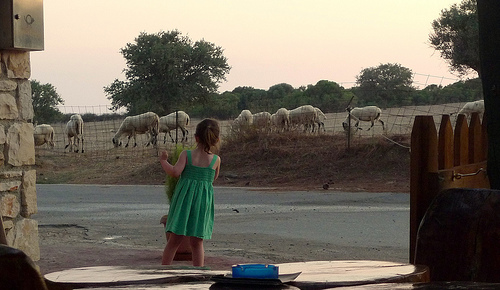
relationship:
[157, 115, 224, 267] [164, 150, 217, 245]
girl wearing dress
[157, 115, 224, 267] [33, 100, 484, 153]
girl watching flock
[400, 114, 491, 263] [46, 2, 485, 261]
gate at entrance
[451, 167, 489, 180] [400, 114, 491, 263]
handle on gate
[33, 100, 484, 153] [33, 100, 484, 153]
flock of flock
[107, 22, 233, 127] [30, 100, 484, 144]
tree in field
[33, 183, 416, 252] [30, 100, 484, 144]
road beside field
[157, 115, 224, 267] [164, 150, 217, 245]
girl in dress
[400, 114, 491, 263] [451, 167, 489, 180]
gate with latch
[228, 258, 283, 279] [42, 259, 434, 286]
ashtray on table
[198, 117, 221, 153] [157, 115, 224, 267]
hair on girl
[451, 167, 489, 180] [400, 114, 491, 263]
hook on gate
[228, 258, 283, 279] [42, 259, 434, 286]
ashtray sitting on table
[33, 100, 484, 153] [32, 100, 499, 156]
flock behind fence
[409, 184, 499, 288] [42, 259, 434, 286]
chair at table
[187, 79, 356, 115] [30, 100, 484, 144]
trees in field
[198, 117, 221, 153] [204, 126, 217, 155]
hair in ponytail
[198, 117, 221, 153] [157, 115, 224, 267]
hair of girl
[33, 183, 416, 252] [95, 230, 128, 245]
street has water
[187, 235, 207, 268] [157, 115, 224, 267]
leg of girl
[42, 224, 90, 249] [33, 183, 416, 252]
dirt on ground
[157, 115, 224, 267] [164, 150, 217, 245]
girl in sundress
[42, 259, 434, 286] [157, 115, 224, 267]
table behind girl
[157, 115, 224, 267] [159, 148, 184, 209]
girl standing behind plant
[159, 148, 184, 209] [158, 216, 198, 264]
plant in flower pot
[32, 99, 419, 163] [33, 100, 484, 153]
flock of flock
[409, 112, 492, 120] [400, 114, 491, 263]
top of gate